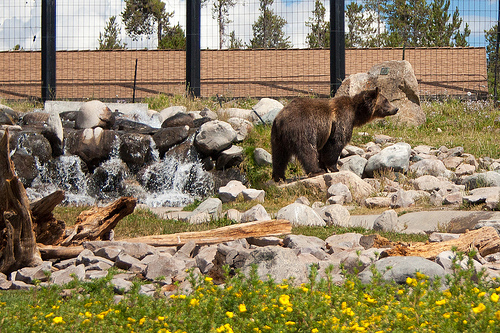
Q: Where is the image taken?
A: Zoo.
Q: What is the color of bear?
A: Brown.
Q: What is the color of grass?
A: Green.